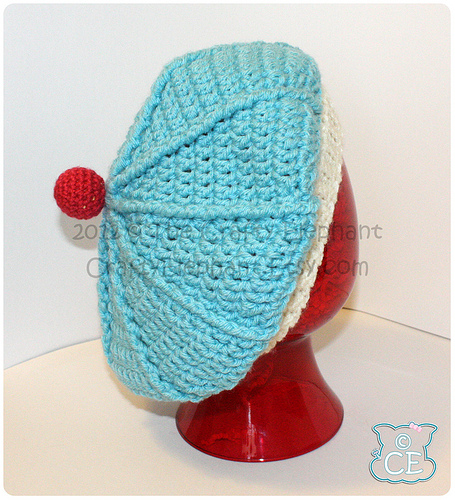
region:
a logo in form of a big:
[366, 404, 445, 491]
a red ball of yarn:
[50, 155, 103, 221]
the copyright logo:
[391, 431, 418, 452]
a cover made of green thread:
[119, 44, 276, 396]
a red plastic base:
[188, 381, 329, 455]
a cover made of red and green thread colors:
[58, 74, 321, 386]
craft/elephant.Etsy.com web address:
[81, 251, 376, 282]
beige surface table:
[7, 395, 149, 497]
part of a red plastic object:
[273, 346, 338, 454]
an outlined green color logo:
[362, 403, 447, 486]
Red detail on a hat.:
[32, 146, 120, 227]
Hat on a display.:
[26, 57, 425, 467]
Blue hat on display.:
[89, 67, 315, 401]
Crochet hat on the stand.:
[49, 41, 413, 371]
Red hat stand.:
[57, 128, 365, 493]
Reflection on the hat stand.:
[157, 358, 305, 476]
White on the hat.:
[145, 74, 396, 360]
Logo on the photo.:
[342, 399, 449, 483]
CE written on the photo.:
[344, 405, 429, 493]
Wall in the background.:
[32, 31, 400, 221]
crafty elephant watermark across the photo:
[55, 196, 397, 305]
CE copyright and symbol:
[359, 412, 444, 490]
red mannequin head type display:
[244, 174, 369, 473]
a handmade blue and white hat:
[73, 48, 367, 406]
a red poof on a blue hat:
[32, 156, 145, 236]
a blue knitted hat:
[110, 81, 351, 337]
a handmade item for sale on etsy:
[64, 42, 431, 482]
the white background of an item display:
[359, 60, 428, 212]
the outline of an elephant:
[353, 404, 442, 492]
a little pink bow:
[402, 412, 429, 441]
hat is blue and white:
[52, 35, 361, 402]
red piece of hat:
[34, 162, 117, 221]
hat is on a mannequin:
[17, 38, 399, 485]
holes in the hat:
[125, 81, 351, 461]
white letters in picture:
[383, 446, 433, 483]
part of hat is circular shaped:
[45, 159, 117, 220]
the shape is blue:
[359, 409, 444, 490]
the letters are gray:
[62, 212, 395, 291]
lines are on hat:
[78, 110, 310, 389]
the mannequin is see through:
[170, 178, 443, 432]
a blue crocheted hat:
[31, 28, 386, 462]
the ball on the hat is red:
[52, 157, 113, 222]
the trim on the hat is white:
[249, 36, 353, 368]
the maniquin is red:
[158, 126, 353, 479]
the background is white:
[54, 26, 100, 114]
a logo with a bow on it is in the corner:
[358, 422, 451, 488]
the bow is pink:
[397, 409, 424, 436]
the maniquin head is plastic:
[174, 145, 395, 483]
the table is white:
[364, 340, 423, 400]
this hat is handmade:
[4, 35, 370, 473]